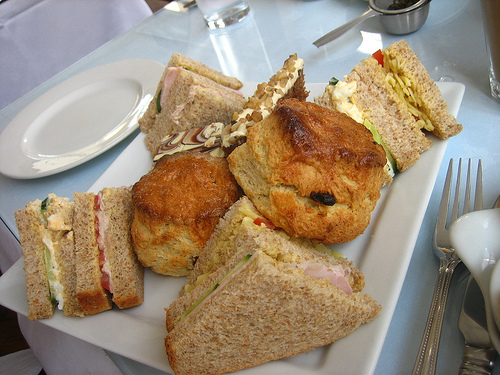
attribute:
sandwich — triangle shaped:
[161, 204, 386, 356]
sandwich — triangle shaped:
[135, 48, 243, 151]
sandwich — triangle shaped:
[6, 181, 139, 304]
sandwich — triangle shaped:
[314, 43, 463, 160]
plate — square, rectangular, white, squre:
[3, 57, 464, 366]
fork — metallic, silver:
[401, 154, 484, 374]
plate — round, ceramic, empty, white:
[0, 50, 173, 182]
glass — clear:
[480, 0, 498, 99]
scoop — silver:
[309, 1, 430, 46]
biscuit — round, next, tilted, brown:
[223, 101, 375, 228]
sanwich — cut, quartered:
[10, 185, 142, 318]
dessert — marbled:
[172, 64, 314, 139]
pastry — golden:
[384, 69, 418, 111]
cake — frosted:
[247, 56, 305, 114]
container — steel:
[364, 0, 439, 33]